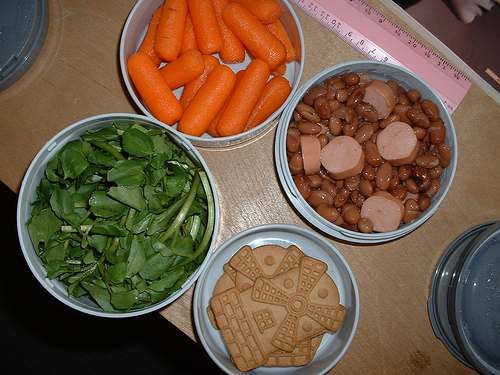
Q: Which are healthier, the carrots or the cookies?
A: The carrots are healthier than the cookies.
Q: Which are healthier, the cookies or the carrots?
A: The carrots are healthier than the cookies.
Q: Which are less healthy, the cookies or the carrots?
A: The cookies are less healthy than the carrots.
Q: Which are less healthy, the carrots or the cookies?
A: The cookies are less healthy than the carrots.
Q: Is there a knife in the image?
A: No, there are no knives.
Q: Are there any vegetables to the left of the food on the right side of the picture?
A: Yes, there is a vegetable to the left of the food.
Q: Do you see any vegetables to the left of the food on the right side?
A: Yes, there is a vegetable to the left of the food.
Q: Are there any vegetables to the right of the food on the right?
A: No, the vegetable is to the left of the food.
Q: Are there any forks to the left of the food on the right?
A: No, there is a vegetable to the left of the food.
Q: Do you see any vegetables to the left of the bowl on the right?
A: Yes, there is a vegetable to the left of the bowl.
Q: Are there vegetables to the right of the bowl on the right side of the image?
A: No, the vegetable is to the left of the bowl.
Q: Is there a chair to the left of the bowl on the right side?
A: No, there is a vegetable to the left of the bowl.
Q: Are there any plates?
A: Yes, there is a plate.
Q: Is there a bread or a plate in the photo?
A: Yes, there is a plate.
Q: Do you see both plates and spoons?
A: No, there is a plate but no spoons.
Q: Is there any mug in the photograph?
A: No, there are no mugs.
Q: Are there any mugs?
A: No, there are no mugs.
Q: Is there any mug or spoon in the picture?
A: No, there are no mugs or spoons.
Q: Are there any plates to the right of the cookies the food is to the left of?
A: Yes, there is a plate to the right of the cookies.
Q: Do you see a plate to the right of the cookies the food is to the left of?
A: Yes, there is a plate to the right of the cookies.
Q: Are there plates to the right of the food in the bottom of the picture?
A: Yes, there is a plate to the right of the cookies.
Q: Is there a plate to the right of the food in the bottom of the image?
A: Yes, there is a plate to the right of the cookies.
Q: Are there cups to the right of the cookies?
A: No, there is a plate to the right of the cookies.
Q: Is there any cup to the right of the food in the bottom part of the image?
A: No, there is a plate to the right of the cookies.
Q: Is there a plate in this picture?
A: Yes, there is a plate.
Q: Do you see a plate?
A: Yes, there is a plate.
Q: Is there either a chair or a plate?
A: Yes, there is a plate.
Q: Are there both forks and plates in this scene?
A: No, there is a plate but no forks.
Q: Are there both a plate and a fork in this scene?
A: No, there is a plate but no forks.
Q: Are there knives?
A: No, there are no knives.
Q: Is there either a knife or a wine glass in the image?
A: No, there are no knives or wine glasses.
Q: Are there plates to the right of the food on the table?
A: Yes, there is a plate to the right of the food.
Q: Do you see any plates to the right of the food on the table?
A: Yes, there is a plate to the right of the food.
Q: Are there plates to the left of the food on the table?
A: No, the plate is to the right of the food.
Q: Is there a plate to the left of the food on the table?
A: No, the plate is to the right of the food.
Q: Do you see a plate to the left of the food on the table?
A: No, the plate is to the right of the food.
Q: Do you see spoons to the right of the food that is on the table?
A: No, there is a plate to the right of the food.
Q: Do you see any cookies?
A: Yes, there are cookies.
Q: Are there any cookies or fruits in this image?
A: Yes, there are cookies.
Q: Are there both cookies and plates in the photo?
A: Yes, there are both cookies and a plate.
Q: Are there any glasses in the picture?
A: No, there are no glasses.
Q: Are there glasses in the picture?
A: No, there are no glasses.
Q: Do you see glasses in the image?
A: No, there are no glasses.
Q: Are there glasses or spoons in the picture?
A: No, there are no glasses or spoons.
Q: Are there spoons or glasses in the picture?
A: No, there are no glasses or spoons.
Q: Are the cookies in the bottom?
A: Yes, the cookies are in the bottom of the image.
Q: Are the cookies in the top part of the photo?
A: No, the cookies are in the bottom of the image.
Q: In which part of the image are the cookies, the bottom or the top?
A: The cookies are in the bottom of the image.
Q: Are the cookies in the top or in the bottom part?
A: The cookies are in the bottom of the image.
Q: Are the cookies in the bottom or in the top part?
A: The cookies are in the bottom of the image.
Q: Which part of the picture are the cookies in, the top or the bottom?
A: The cookies are in the bottom of the image.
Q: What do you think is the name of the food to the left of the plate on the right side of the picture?
A: The food is cookies.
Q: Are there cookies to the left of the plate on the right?
A: Yes, there are cookies to the left of the plate.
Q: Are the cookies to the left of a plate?
A: Yes, the cookies are to the left of a plate.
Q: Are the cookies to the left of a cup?
A: No, the cookies are to the left of a plate.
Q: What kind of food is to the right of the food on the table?
A: The food is cookies.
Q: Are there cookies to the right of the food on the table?
A: Yes, there are cookies to the right of the food.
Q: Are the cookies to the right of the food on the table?
A: Yes, the cookies are to the right of the food.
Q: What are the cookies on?
A: The cookies are on the plate.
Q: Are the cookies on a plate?
A: Yes, the cookies are on a plate.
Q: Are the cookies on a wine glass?
A: No, the cookies are on a plate.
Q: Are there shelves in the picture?
A: No, there are no shelves.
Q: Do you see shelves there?
A: No, there are no shelves.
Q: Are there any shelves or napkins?
A: No, there are no shelves or napkins.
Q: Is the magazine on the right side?
A: Yes, the magazine is on the right of the image.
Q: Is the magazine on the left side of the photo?
A: No, the magazine is on the right of the image.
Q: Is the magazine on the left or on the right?
A: The magazine is on the right of the image.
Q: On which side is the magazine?
A: The magazine is on the right of the image.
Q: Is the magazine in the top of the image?
A: Yes, the magazine is in the top of the image.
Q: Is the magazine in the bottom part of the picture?
A: No, the magazine is in the top of the image.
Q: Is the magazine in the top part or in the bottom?
A: The magazine is in the top of the image.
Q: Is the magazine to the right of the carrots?
A: Yes, the magazine is to the right of the carrots.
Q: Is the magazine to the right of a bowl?
A: Yes, the magazine is to the right of a bowl.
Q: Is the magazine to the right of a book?
A: No, the magazine is to the right of a bowl.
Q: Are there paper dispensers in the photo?
A: No, there are no paper dispensers.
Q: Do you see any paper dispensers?
A: No, there are no paper dispensers.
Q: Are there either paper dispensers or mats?
A: No, there are no paper dispensers or mats.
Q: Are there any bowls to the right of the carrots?
A: Yes, there is a bowl to the right of the carrots.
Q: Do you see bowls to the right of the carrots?
A: Yes, there is a bowl to the right of the carrots.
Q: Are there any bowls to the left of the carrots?
A: No, the bowl is to the right of the carrots.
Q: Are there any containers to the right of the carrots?
A: No, there is a bowl to the right of the carrots.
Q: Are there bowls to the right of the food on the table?
A: Yes, there is a bowl to the right of the food.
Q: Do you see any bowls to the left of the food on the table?
A: No, the bowl is to the right of the food.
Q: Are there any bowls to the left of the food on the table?
A: No, the bowl is to the right of the food.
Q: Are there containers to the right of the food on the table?
A: No, there is a bowl to the right of the food.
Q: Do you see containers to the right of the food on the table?
A: No, there is a bowl to the right of the food.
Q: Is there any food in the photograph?
A: Yes, there is food.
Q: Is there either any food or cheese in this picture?
A: Yes, there is food.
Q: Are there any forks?
A: No, there are no forks.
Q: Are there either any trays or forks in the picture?
A: No, there are no forks or trays.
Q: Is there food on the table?
A: Yes, there is food on the table.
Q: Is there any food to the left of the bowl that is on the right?
A: Yes, there is food to the left of the bowl.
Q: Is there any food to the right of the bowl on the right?
A: No, the food is to the left of the bowl.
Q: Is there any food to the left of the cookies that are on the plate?
A: Yes, there is food to the left of the cookies.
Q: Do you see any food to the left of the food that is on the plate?
A: Yes, there is food to the left of the cookies.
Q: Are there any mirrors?
A: No, there are no mirrors.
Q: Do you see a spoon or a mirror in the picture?
A: No, there are no mirrors or spoons.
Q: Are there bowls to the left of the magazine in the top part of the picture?
A: Yes, there is a bowl to the left of the magazine.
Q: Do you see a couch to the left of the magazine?
A: No, there is a bowl to the left of the magazine.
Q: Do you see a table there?
A: Yes, there is a table.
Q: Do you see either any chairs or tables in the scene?
A: Yes, there is a table.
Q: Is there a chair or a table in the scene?
A: Yes, there is a table.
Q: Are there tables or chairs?
A: Yes, there is a table.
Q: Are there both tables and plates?
A: Yes, there are both a table and a plate.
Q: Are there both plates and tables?
A: Yes, there are both a table and a plate.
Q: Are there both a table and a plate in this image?
A: Yes, there are both a table and a plate.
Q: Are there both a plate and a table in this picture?
A: Yes, there are both a table and a plate.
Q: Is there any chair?
A: No, there are no chairs.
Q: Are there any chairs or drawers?
A: No, there are no chairs or drawers.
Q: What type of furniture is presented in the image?
A: The furniture is a table.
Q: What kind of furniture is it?
A: The piece of furniture is a table.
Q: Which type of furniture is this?
A: This is a table.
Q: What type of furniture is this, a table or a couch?
A: This is a table.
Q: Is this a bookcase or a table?
A: This is a table.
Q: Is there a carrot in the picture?
A: Yes, there are carrots.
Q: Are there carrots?
A: Yes, there are carrots.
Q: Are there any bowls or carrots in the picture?
A: Yes, there are carrots.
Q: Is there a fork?
A: No, there are no forks.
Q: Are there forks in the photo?
A: No, there are no forks.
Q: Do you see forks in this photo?
A: No, there are no forks.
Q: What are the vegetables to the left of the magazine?
A: The vegetables are carrots.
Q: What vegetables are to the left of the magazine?
A: The vegetables are carrots.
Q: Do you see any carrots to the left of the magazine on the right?
A: Yes, there are carrots to the left of the magazine.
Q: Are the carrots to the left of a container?
A: No, the carrots are to the left of the magazine.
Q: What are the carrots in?
A: The carrots are in the bowl.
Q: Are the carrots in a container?
A: No, the carrots are in a bowl.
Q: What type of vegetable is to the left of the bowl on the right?
A: The vegetables are carrots.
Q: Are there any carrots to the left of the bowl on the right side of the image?
A: Yes, there are carrots to the left of the bowl.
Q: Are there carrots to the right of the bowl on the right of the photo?
A: No, the carrots are to the left of the bowl.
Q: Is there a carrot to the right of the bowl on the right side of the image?
A: No, the carrots are to the left of the bowl.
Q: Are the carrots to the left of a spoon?
A: No, the carrots are to the left of the bowl.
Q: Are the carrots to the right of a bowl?
A: No, the carrots are to the left of a bowl.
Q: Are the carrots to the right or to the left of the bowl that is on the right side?
A: The carrots are to the left of the bowl.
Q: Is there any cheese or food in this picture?
A: Yes, there is food.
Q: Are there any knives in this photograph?
A: No, there are no knives.